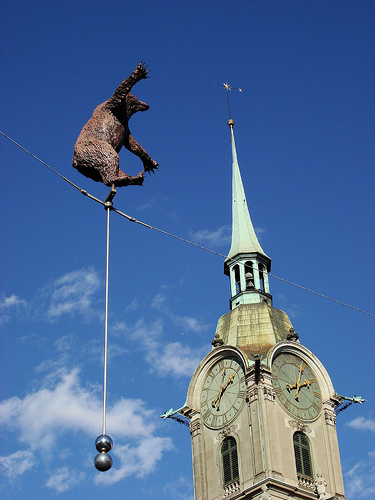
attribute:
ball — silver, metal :
[94, 450, 110, 473]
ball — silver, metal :
[96, 435, 113, 449]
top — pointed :
[212, 78, 281, 301]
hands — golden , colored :
[288, 363, 312, 402]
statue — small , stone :
[313, 475, 332, 498]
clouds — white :
[10, 397, 100, 429]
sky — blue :
[281, 116, 283, 124]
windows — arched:
[215, 428, 314, 490]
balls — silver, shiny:
[95, 433, 112, 471]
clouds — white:
[7, 263, 213, 497]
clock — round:
[271, 353, 324, 421]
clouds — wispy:
[6, 220, 363, 494]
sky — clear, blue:
[4, 10, 363, 490]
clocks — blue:
[200, 352, 324, 423]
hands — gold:
[285, 360, 314, 399]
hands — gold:
[210, 364, 234, 410]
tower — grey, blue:
[155, 81, 357, 497]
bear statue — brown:
[71, 61, 160, 186]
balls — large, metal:
[94, 434, 113, 470]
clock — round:
[199, 357, 248, 428]